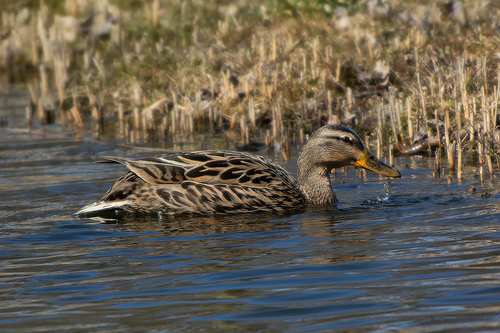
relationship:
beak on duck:
[351, 149, 401, 179] [78, 90, 390, 237]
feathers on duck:
[133, 157, 313, 244] [79, 121, 402, 229]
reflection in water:
[72, 204, 372, 240] [2, 217, 498, 326]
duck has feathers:
[70, 110, 414, 237] [102, 153, 277, 195]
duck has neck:
[70, 122, 404, 220] [296, 155, 333, 207]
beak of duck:
[340, 137, 412, 187] [69, 120, 477, 220]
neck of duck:
[296, 156, 340, 204] [70, 122, 404, 220]